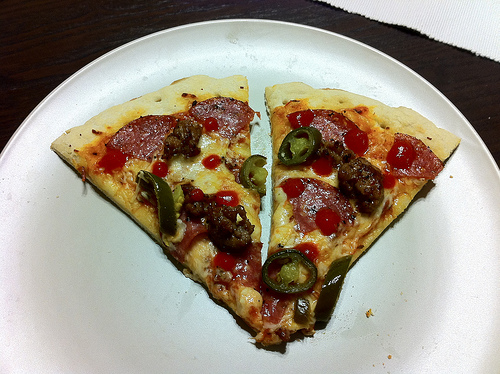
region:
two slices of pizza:
[51, 74, 459, 346]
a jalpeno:
[275, 130, 317, 165]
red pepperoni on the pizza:
[122, 126, 164, 153]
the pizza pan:
[10, 246, 166, 356]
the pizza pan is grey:
[380, 275, 475, 360]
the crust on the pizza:
[150, 85, 177, 105]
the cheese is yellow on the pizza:
[271, 215, 286, 240]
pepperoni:
[211, 256, 241, 271]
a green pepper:
[322, 263, 343, 291]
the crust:
[377, 109, 417, 131]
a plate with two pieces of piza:
[38, 65, 498, 231]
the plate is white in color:
[383, 244, 478, 353]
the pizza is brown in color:
[82, 118, 246, 300]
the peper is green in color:
[139, 172, 176, 222]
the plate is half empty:
[121, 28, 446, 371]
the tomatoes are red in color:
[288, 174, 323, 237]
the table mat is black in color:
[391, 35, 493, 102]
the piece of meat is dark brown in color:
[211, 205, 251, 250]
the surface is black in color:
[376, 0, 478, 24]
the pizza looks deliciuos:
[112, 95, 316, 264]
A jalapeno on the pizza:
[261, 250, 313, 296]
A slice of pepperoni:
[113, 109, 183, 161]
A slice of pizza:
[262, 86, 459, 334]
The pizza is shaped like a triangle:
[260, 88, 461, 333]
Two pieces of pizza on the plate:
[47, 75, 459, 349]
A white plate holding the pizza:
[1, 18, 493, 370]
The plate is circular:
[1, 19, 499, 372]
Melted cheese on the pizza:
[278, 211, 289, 235]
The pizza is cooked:
[53, 74, 461, 343]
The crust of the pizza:
[262, 84, 455, 161]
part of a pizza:
[336, 238, 375, 269]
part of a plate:
[356, 299, 389, 356]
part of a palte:
[380, 273, 425, 343]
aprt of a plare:
[387, 300, 414, 335]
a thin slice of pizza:
[53, 70, 263, 335]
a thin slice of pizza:
[262, 83, 462, 336]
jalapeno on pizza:
[263, 248, 316, 291]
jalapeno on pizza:
[277, 128, 319, 165]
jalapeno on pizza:
[237, 153, 265, 190]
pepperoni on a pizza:
[114, 115, 195, 163]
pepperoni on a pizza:
[388, 130, 441, 177]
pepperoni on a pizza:
[192, 94, 254, 136]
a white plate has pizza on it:
[1, 20, 498, 372]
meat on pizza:
[193, 198, 250, 248]